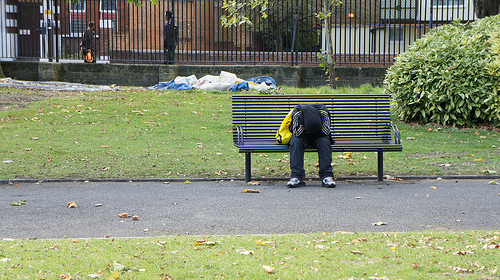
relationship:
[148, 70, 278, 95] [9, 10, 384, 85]
garbage in background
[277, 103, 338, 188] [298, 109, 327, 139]
man wearing hood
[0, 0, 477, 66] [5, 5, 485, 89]
fence in background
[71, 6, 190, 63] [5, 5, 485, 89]
people in background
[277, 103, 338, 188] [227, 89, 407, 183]
man sitting on bench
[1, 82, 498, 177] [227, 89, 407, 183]
grass behind bench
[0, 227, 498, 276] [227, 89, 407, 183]
grass in front of bench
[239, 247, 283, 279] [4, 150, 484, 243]
leaves covering ground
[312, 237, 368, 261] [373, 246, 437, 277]
leaves covering ground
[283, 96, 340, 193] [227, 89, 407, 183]
man sitting on bench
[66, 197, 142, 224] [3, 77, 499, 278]
leaves covering ground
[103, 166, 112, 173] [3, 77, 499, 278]
leaf covering ground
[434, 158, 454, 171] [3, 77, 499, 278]
leaf covering ground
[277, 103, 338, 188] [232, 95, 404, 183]
man sitting on bench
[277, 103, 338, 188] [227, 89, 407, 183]
man bent over bench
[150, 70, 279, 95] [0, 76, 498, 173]
garbage in field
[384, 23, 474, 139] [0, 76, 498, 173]
bush growing in field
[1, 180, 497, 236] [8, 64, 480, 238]
path in park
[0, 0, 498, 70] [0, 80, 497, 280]
fence around park